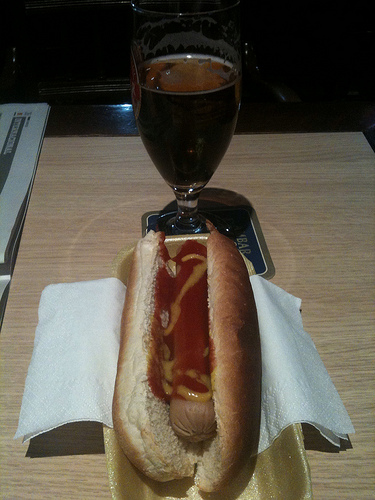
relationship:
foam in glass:
[143, 46, 239, 74] [139, 37, 251, 265]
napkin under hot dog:
[12, 274, 354, 458] [112, 227, 262, 493]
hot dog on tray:
[112, 227, 262, 493] [102, 234, 313, 498]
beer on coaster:
[130, 53, 240, 199] [135, 202, 274, 285]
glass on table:
[129, 1, 244, 235] [3, 123, 373, 499]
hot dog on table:
[112, 227, 261, 497] [3, 123, 373, 499]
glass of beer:
[129, 1, 252, 248] [130, 53, 240, 199]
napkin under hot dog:
[56, 274, 339, 432] [112, 227, 262, 493]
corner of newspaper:
[37, 100, 55, 114] [0, 102, 53, 326]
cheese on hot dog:
[156, 248, 209, 345] [50, 188, 280, 488]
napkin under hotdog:
[12, 274, 354, 458] [160, 235, 215, 444]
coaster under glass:
[135, 202, 274, 285] [121, 2, 248, 254]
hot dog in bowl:
[112, 227, 262, 493] [100, 231, 312, 498]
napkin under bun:
[12, 274, 354, 458] [112, 223, 262, 498]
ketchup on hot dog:
[158, 237, 209, 399] [128, 229, 252, 480]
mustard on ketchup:
[160, 252, 208, 335] [158, 235, 206, 389]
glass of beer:
[129, 1, 244, 235] [130, 53, 240, 199]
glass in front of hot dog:
[129, 1, 244, 235] [114, 228, 264, 383]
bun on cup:
[112, 223, 262, 498] [99, 245, 322, 498]